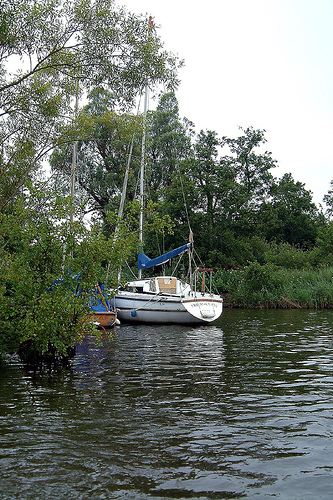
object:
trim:
[150, 277, 176, 294]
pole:
[137, 237, 190, 261]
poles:
[63, 65, 84, 293]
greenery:
[0, 0, 333, 364]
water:
[163, 351, 326, 497]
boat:
[52, 266, 117, 328]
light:
[189, 4, 284, 42]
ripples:
[149, 359, 218, 403]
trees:
[179, 126, 252, 231]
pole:
[137, 14, 155, 277]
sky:
[213, 40, 283, 92]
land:
[234, 263, 315, 306]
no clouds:
[276, 72, 327, 128]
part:
[133, 241, 198, 273]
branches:
[163, 125, 264, 208]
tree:
[267, 172, 318, 240]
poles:
[190, 267, 214, 296]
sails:
[105, 16, 197, 280]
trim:
[117, 290, 222, 324]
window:
[115, 285, 144, 293]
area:
[170, 149, 323, 322]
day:
[0, 0, 333, 500]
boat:
[106, 243, 224, 324]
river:
[0, 356, 333, 497]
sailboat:
[45, 53, 117, 330]